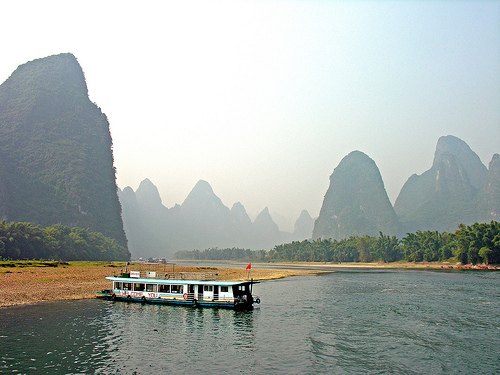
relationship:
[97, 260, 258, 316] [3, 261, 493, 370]
boat on blue water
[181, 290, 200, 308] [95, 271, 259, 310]
rail on boat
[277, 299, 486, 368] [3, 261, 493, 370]
waves in blue water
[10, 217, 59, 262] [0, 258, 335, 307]
tree on beach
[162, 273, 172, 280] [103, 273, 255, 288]
inflation device on deck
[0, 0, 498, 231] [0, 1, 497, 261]
sky has cloud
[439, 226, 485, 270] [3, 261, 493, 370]
tree behind blue water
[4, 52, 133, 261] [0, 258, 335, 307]
hill on beach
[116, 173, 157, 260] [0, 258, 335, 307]
hill on beach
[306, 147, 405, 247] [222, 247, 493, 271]
hill on side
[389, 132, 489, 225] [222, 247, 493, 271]
hill on side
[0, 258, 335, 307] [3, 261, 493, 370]
beach of blue water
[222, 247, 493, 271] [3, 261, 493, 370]
side of blue water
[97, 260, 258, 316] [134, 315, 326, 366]
boat on water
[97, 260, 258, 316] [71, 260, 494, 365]
boat on water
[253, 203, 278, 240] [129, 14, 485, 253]
mountain in distance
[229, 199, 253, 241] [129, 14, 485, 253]
mountain in distance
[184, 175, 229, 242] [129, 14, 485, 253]
mountain in distance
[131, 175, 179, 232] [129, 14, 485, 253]
mountain in distance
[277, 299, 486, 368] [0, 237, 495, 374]
waves in water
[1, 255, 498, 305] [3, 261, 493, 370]
shore next to blue water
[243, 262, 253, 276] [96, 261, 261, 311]
flag on boat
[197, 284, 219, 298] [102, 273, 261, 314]
door on boat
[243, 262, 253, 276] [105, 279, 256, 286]
flag on top of roof